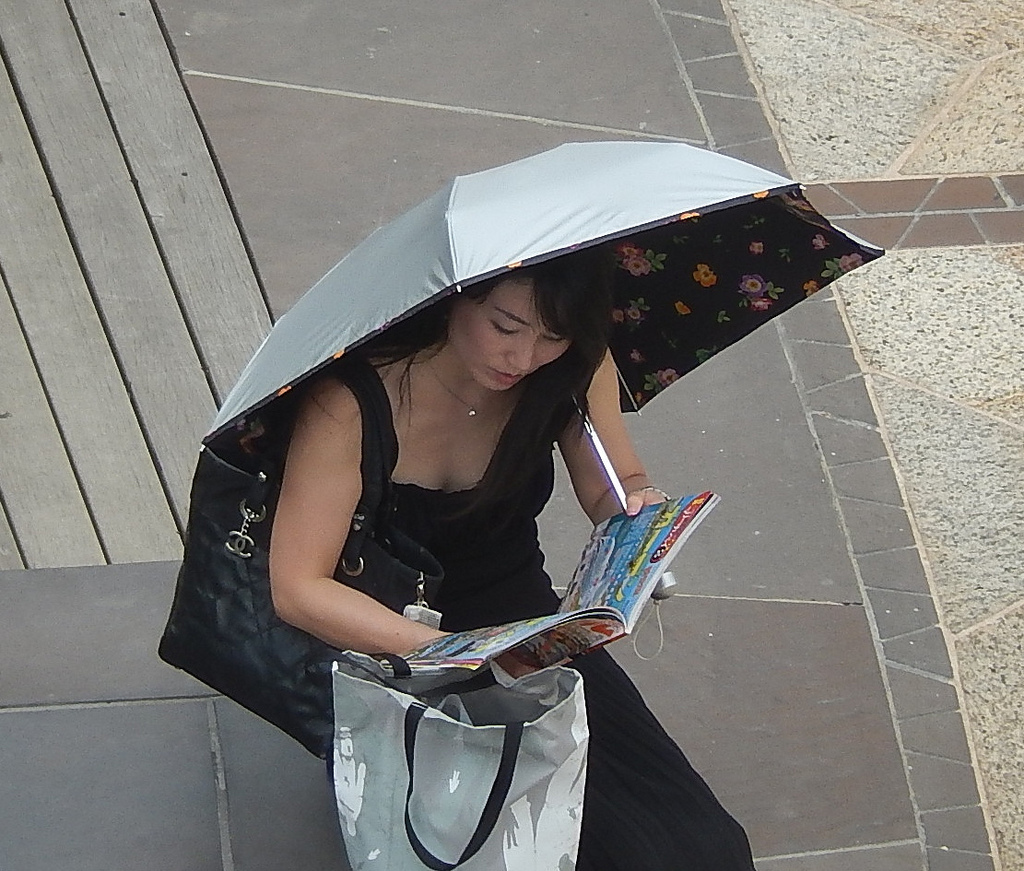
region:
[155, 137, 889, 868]
A woman holding a silver and black umbrella.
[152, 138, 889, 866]
A woman wearing a black dress.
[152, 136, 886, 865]
A woman with a black back hung on her shoulder.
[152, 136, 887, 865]
A woman reading a magazine.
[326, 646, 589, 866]
A gray and white bag with black handles.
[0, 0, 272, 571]
A section of sidewalk is wood.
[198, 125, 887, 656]
Underside of umbrella is flower patterned.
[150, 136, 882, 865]
A woman wearing a very thin neacklace.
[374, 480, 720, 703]
Colorful magazine is open.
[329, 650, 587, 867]
White canvas bag with black strap.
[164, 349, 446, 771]
Black purse hanging over shoulder.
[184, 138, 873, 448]
Woman under silver and black umbrella.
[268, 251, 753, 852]
Woman holding open magazine.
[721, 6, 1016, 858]
Gray, brown and white walkway.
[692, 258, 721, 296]
Flower design on underside of umbrella.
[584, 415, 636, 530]
Metal pole for umbrella.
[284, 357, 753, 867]
Black, low-cut dress.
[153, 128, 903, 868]
woman is sitting under an umbrella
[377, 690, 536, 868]
black strap on the bag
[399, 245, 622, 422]
head is bent down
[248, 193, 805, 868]
woman is looking at a magazine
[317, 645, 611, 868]
gray and white bag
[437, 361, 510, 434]
woman is wearing a necklace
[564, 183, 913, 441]
design on the inside of the umbrella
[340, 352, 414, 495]
black strap over the shoulder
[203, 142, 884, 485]
Umbrella with flowers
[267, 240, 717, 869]
Woman is holding a magazine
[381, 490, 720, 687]
Magazine is colorful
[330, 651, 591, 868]
Bag is grey with black handles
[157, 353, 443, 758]
A black bag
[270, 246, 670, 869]
Woman has dark hair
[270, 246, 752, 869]
Woman reading a magazine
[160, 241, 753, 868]
Woman is holding a black bag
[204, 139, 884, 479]
Umbrella is silver on one side and covered with flowers on the other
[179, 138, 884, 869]
Woman is holding an umbrella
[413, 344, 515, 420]
Woman is wearing a necklace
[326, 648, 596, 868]
White and grey bag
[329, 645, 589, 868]
Bag with black handles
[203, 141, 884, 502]
Silver umbrella with flower print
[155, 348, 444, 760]
Black purse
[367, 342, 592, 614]
Woman is wearing a black shirt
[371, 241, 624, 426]
Woman has dark hair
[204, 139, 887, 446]
Woman sitting under the umbrella.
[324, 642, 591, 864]
Gray bag beside the girl.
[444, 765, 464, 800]
Arrow on the bag.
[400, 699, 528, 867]
Strap on the bag.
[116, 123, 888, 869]
Woman with umbrella, magazine and shopping bags.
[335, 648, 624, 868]
White tote bag with black handles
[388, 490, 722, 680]
Magazine and woman's arms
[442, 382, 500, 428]
charm on a necklace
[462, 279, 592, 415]
woman's face as she reads magazine.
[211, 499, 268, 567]
Charm on a tote bag.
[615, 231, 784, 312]
Pattern on the underside of an umbrella.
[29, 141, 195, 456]
Pattern on a sidewalk.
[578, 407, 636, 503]
Handle of an umbrella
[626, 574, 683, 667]
Loop of an umbrella.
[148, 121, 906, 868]
woman holds a magazine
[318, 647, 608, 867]
the bag has black straps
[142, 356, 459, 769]
the purse is black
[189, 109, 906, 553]
an umbrella behind a woman